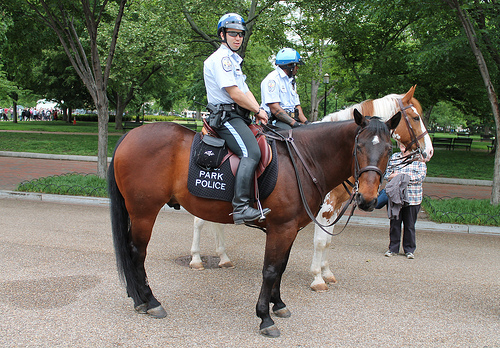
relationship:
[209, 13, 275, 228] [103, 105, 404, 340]
police officer on horse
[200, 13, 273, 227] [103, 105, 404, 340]
police officer on horse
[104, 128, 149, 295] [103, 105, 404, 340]
black tail on horse